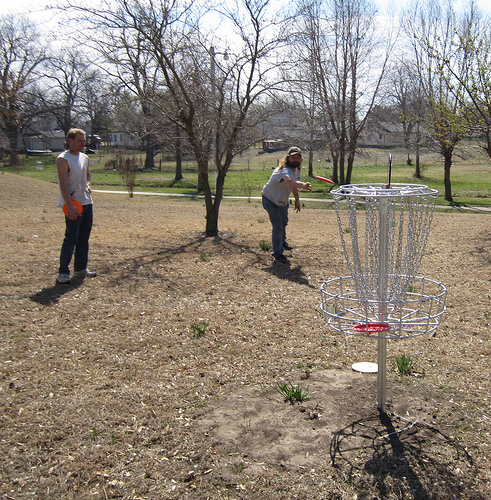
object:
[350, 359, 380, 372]
disk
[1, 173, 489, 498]
ground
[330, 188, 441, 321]
chains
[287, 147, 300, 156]
hat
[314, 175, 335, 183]
disk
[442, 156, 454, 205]
tree trunk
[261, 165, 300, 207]
tshirt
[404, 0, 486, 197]
tree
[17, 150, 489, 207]
grass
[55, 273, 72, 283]
shoes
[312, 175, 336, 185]
orange frisbee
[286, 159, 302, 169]
beard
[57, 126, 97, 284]
man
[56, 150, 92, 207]
shirt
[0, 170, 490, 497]
dirt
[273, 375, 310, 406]
grass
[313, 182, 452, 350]
container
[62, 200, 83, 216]
frisbee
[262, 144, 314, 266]
guy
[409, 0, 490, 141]
leaves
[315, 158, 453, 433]
frisbee catcher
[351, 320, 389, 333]
frisbee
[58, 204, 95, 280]
jeans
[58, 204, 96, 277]
blue jeans